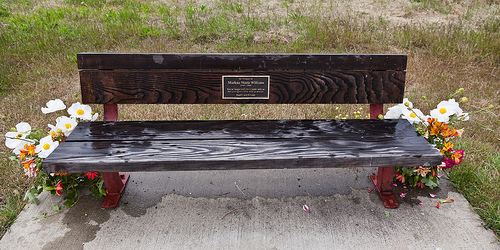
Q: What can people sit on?
A: Bench.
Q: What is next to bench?
A: Flowers.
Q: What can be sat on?
A: Bench.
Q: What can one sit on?
A: Bench.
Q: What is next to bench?
A: Flowers.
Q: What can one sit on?
A: Bench.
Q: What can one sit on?
A: Bench.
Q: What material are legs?
A: Metal.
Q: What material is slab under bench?
A: Concrete.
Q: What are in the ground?
A: Flowers.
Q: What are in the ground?
A: Slab.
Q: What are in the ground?
A: Bench.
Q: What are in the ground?
A: Flowers.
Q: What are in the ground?
A: Bench.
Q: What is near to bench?
A: Flowers.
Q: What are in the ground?
A: Bench.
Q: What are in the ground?
A: Grass.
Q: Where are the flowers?
A: On either side of the bench.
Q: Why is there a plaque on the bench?
A: It is a memorial.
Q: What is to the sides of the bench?
A: Flowers.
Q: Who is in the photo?
A: No one.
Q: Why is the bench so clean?
A: It was just made.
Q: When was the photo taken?
A: Daytime.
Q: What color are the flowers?
A: Yellow and white.